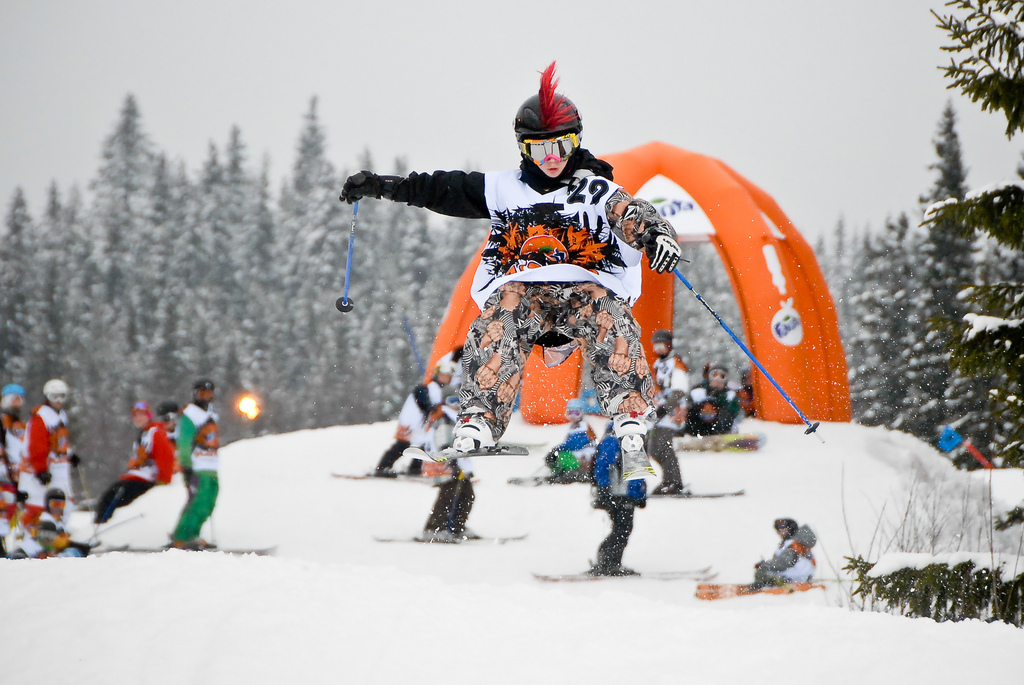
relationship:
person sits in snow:
[689, 506, 834, 615] [67, 573, 835, 654]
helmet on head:
[537, 60, 580, 131] [516, 89, 583, 174]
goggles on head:
[518, 129, 584, 166] [516, 89, 583, 174]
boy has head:
[334, 88, 678, 460] [516, 89, 583, 174]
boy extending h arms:
[338, 94, 682, 482] [344, 142, 675, 238]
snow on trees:
[183, 214, 300, 307] [26, 83, 493, 537]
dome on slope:
[656, 152, 896, 457] [587, 374, 1018, 658]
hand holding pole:
[643, 234, 710, 295] [656, 236, 849, 446]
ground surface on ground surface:
[0, 409, 1024, 684] [60, 426, 989, 669]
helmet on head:
[508, 74, 588, 139] [513, 93, 584, 178]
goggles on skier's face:
[516, 119, 592, 172] [514, 95, 586, 191]